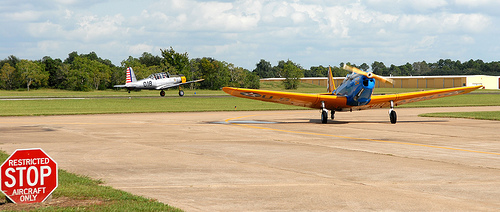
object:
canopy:
[152, 73, 169, 80]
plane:
[219, 63, 486, 124]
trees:
[63, 53, 101, 91]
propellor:
[338, 61, 396, 91]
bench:
[395, 172, 406, 185]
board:
[3, 148, 60, 205]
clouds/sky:
[0, 0, 500, 71]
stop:
[2, 145, 57, 203]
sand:
[143, 127, 302, 184]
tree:
[278, 60, 301, 91]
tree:
[191, 57, 231, 90]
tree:
[160, 47, 190, 86]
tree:
[65, 57, 112, 90]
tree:
[10, 58, 49, 88]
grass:
[57, 193, 151, 210]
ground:
[0, 77, 500, 212]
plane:
[113, 66, 207, 97]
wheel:
[390, 109, 396, 124]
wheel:
[319, 109, 329, 124]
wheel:
[329, 113, 335, 120]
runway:
[0, 105, 500, 212]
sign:
[0, 147, 59, 204]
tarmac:
[0, 89, 500, 212]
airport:
[1, 46, 500, 212]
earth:
[0, 149, 177, 212]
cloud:
[368, 9, 488, 38]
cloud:
[22, 21, 125, 44]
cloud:
[165, 7, 257, 34]